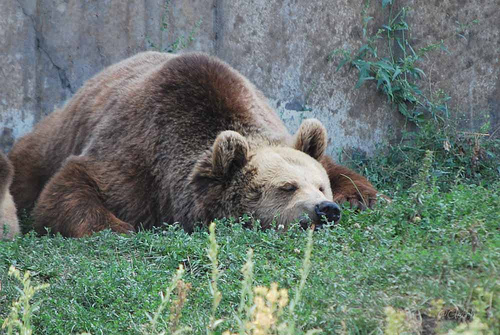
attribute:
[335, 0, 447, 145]
weeds — spikey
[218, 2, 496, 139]
wall — cement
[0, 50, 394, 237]
bear — brown, sleeping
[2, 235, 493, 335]
grass — short, green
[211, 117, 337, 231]
head — light-brown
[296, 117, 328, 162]
ear — rounded, brown, furry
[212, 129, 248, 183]
ear — rounded, light-brown, furry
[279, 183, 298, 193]
eye — closed, black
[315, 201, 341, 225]
nose — black